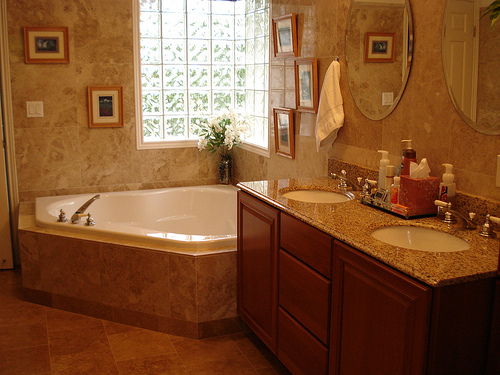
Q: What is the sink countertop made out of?
A: Granite.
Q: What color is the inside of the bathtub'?
A: White.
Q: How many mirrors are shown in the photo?
A: Two.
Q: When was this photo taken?
A: Day time.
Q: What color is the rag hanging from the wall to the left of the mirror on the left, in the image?
A: White.